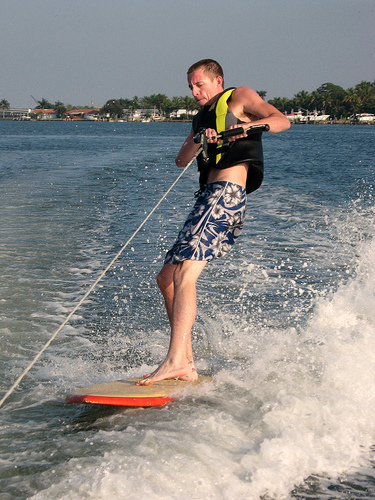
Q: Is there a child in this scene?
A: No, there are no children.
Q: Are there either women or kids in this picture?
A: No, there are no kids or women.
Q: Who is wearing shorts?
A: The man is wearing shorts.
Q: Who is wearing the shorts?
A: The man is wearing shorts.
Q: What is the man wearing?
A: The man is wearing shorts.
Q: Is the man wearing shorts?
A: Yes, the man is wearing shorts.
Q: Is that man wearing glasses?
A: No, the man is wearing shorts.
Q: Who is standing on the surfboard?
A: The man is standing on the surfboard.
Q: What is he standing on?
A: The man is standing on the surfboard.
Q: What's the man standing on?
A: The man is standing on the surfboard.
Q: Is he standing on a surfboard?
A: Yes, the man is standing on a surfboard.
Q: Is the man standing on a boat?
A: No, the man is standing on a surfboard.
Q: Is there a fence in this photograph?
A: No, there are no fences.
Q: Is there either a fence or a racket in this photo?
A: No, there are no fences or rackets.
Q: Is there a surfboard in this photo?
A: Yes, there is a surfboard.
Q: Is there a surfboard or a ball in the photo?
A: Yes, there is a surfboard.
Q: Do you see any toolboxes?
A: No, there are no toolboxes.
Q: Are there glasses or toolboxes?
A: No, there are no toolboxes or glasses.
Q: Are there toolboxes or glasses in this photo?
A: No, there are no toolboxes or glasses.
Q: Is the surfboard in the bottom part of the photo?
A: Yes, the surfboard is in the bottom of the image.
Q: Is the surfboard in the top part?
A: No, the surfboard is in the bottom of the image.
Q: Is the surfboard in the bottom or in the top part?
A: The surfboard is in the bottom of the image.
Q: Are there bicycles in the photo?
A: No, there are no bicycles.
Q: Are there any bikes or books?
A: No, there are no bikes or books.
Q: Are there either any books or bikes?
A: No, there are no bikes or books.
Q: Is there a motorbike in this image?
A: No, there are no motorcycles.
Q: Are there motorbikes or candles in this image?
A: No, there are no motorbikes or candles.